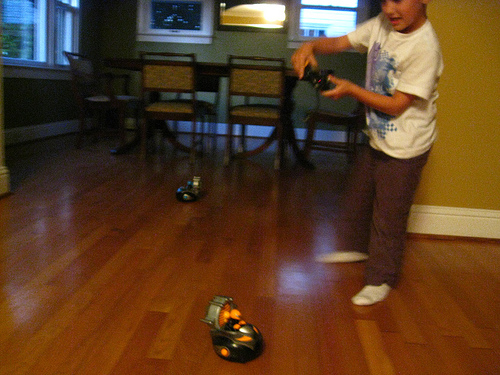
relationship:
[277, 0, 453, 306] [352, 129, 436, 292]
boy in pants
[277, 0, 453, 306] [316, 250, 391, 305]
boy in socks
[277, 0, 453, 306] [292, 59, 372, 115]
boy holding remote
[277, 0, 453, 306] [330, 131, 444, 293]
boy in pants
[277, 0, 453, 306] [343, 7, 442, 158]
boy in t-shirt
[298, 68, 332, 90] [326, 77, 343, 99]
remote in hand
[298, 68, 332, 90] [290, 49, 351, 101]
remote in hands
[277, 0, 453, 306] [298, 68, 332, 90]
boy hold remote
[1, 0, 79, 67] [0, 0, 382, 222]
window in dining room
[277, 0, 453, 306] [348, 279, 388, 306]
boy wears sock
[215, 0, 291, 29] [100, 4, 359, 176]
mirror on wall